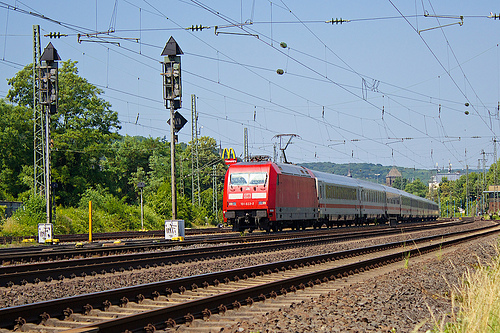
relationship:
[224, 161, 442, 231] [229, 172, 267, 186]
train has windshield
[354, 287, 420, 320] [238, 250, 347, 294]
gravel beside track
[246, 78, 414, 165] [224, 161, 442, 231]
wires over train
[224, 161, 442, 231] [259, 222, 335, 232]
train has wheels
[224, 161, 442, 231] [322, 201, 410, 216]
train has stripe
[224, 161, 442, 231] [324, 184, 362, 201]
train has windows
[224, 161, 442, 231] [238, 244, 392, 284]
train on tracks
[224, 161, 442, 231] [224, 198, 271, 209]
train has headlights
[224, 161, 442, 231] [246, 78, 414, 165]
train bellow wires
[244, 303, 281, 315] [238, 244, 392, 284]
wood under tracks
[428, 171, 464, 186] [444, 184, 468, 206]
roof behind trees